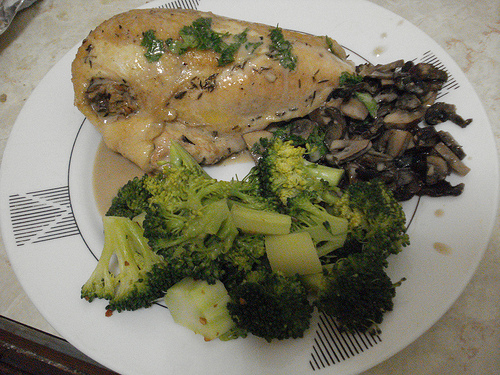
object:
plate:
[0, 0, 498, 375]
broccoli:
[252, 137, 350, 214]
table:
[0, 0, 500, 375]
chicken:
[70, 6, 359, 177]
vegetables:
[263, 23, 300, 72]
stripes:
[31, 231, 81, 245]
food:
[70, 8, 474, 346]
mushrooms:
[326, 136, 376, 164]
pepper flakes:
[198, 316, 209, 326]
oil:
[368, 45, 384, 57]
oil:
[428, 236, 455, 257]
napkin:
[0, 0, 47, 38]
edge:
[0, 52, 53, 323]